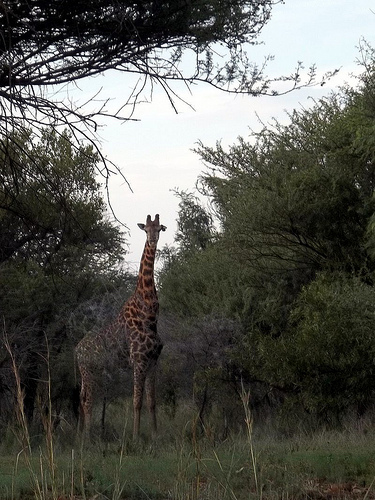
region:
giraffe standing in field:
[50, 209, 178, 459]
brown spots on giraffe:
[129, 306, 151, 342]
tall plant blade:
[228, 373, 277, 498]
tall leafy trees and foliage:
[158, 36, 372, 450]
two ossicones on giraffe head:
[143, 208, 162, 224]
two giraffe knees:
[127, 390, 160, 414]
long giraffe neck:
[135, 248, 158, 284]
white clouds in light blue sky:
[91, 84, 217, 206]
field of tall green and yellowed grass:
[3, 396, 373, 497]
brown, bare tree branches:
[8, 83, 148, 235]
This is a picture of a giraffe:
[47, 188, 183, 439]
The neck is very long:
[74, 190, 196, 306]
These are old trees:
[219, 227, 344, 317]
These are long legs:
[110, 327, 182, 494]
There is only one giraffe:
[83, 307, 159, 414]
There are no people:
[32, 412, 142, 495]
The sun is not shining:
[135, 170, 151, 192]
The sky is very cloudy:
[113, 181, 150, 198]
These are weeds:
[127, 465, 187, 495]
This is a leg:
[114, 400, 137, 429]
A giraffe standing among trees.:
[8, 170, 364, 452]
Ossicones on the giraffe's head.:
[141, 207, 159, 222]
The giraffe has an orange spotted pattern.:
[67, 213, 169, 446]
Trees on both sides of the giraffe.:
[0, 191, 367, 446]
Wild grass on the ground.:
[2, 401, 355, 494]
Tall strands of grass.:
[0, 322, 257, 493]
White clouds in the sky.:
[0, 0, 365, 285]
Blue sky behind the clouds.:
[0, 0, 370, 150]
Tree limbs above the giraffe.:
[0, 0, 347, 229]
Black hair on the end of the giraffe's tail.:
[67, 380, 82, 420]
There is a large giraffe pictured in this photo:
[117, 209, 193, 429]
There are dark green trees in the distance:
[321, 314, 342, 361]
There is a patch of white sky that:
[132, 239, 137, 267]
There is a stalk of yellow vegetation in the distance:
[235, 380, 254, 456]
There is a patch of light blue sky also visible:
[175, 120, 190, 152]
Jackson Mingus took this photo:
[66, 55, 332, 416]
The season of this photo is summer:
[44, 40, 299, 380]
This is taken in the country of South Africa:
[75, 46, 295, 497]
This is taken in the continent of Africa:
[66, 138, 293, 476]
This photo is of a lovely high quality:
[38, 121, 293, 468]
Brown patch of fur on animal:
[142, 268, 156, 277]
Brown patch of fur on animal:
[125, 336, 134, 355]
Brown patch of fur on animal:
[130, 318, 144, 347]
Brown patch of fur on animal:
[142, 304, 156, 331]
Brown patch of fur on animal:
[76, 380, 89, 395]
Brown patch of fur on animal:
[73, 386, 95, 416]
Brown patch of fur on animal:
[129, 401, 164, 430]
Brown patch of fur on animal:
[116, 349, 171, 389]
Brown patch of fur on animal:
[75, 325, 121, 364]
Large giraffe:
[48, 192, 185, 473]